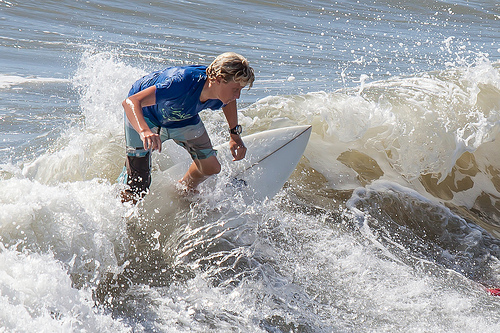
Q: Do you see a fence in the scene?
A: No, there are no fences.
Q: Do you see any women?
A: No, there are no women.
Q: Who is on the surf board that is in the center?
A: The man is on the surf board.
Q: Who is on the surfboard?
A: The man is on the surf board.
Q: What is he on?
A: The man is on the surfboard.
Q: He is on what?
A: The man is on the surfboard.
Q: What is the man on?
A: The man is on the surfboard.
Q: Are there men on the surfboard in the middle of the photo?
A: Yes, there is a man on the surfboard.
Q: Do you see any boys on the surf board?
A: No, there is a man on the surf board.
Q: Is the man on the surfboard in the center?
A: Yes, the man is on the surf board.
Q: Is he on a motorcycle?
A: No, the man is on the surf board.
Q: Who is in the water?
A: The man is in the water.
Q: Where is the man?
A: The man is in the water.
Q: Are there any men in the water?
A: Yes, there is a man in the water.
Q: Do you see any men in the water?
A: Yes, there is a man in the water.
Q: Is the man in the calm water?
A: Yes, the man is in the water.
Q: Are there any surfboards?
A: Yes, there is a surfboard.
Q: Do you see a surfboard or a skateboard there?
A: Yes, there is a surfboard.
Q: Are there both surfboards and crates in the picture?
A: No, there is a surfboard but no crates.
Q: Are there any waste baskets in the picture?
A: No, there are no waste baskets.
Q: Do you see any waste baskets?
A: No, there are no waste baskets.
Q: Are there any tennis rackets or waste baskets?
A: No, there are no waste baskets or tennis rackets.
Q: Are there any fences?
A: No, there are no fences.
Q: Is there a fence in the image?
A: No, there are no fences.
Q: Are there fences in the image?
A: No, there are no fences.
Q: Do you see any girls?
A: No, there are no girls.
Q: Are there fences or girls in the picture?
A: No, there are no girls or fences.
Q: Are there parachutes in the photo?
A: No, there are no parachutes.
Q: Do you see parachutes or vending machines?
A: No, there are no parachutes or vending machines.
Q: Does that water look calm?
A: Yes, the water is calm.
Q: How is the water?
A: The water is calm.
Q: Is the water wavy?
A: No, the water is calm.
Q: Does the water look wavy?
A: No, the water is calm.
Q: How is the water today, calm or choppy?
A: The water is calm.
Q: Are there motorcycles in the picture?
A: No, there are no motorcycles.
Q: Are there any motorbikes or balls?
A: No, there are no motorbikes or balls.